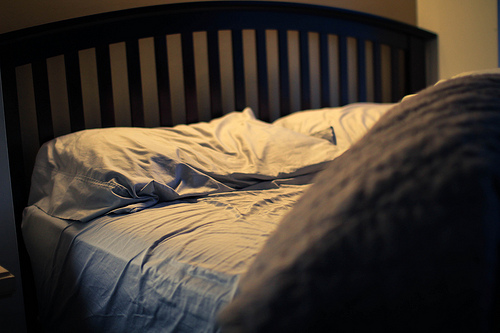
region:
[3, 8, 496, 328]
The bed is unmade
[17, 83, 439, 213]
White pillows are ruffled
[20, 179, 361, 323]
White sheets are wrinkled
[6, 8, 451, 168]
The bed has a wooden head board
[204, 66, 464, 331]
The bed comforter is on top of the bed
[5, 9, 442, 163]
The head board is made of wood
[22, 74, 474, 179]
The bed has two pillows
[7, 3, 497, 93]
The walls are white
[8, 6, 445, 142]
The head board is dark brown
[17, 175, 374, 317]
The bed sheets are white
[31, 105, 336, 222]
a wrinkly pillowcase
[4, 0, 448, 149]
a wooden headboard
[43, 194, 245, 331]
a set of wrinkly sheets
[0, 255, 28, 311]
the corner of a nightstand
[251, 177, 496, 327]
an unidentifable mass in the foreground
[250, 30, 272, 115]
a plank of wood in the headboards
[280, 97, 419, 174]
a half covered pillow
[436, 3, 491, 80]
orange and yellow walls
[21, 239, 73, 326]
the shadow of the nightstand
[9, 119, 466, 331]
a comfortable looking bed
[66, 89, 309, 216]
pillow on the bed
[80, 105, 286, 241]
sheet on the pillow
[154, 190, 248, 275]
wrinkles in the sheet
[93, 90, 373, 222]
two pillows on the bed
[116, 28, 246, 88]
wood behind the pillow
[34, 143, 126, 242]
side of the pillow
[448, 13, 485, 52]
wall next to bed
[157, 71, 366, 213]
bed with no people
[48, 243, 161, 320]
side of the bed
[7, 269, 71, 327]
dark part of the photo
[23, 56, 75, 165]
Small dark wooden slat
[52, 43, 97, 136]
Small dark wooden slat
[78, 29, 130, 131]
Small dark wooden slat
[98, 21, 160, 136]
Small dark wooden slat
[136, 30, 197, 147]
Small dark wooden slat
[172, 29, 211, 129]
Small dark wooden slat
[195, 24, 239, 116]
Small dark wooden slat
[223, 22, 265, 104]
Small dark wooden slat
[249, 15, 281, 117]
Small dark wooden slat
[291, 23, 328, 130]
Small dark wooden slat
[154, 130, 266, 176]
Pillows in the photo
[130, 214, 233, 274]
A bed in the photo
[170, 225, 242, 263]
Bedsheet on the bed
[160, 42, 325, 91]
Wooden bars on the bed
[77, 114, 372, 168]
Pillow covers in the photo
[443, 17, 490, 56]
A wall in the photo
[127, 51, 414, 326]
A bed in the room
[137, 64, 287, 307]
A wooden bed in the photo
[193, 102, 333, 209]
A bed in the room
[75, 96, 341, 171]
Pillows on the bed